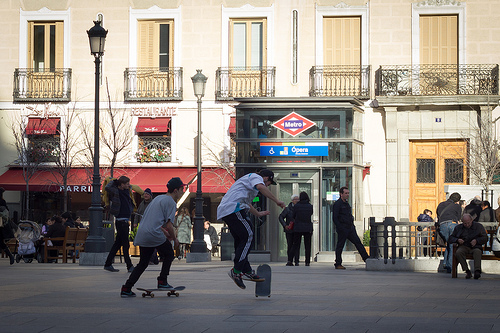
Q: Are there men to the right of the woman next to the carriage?
A: Yes, there is a man to the right of the woman.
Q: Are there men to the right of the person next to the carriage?
A: Yes, there is a man to the right of the woman.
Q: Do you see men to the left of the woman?
A: No, the man is to the right of the woman.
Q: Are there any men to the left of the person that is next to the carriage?
A: No, the man is to the right of the woman.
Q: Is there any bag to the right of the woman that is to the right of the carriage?
A: No, there is a man to the right of the woman.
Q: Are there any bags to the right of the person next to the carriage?
A: No, there is a man to the right of the woman.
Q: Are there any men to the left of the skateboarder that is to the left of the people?
A: Yes, there is a man to the left of the skateboarder.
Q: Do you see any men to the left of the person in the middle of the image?
A: Yes, there is a man to the left of the skateboarder.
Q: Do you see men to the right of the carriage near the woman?
A: Yes, there is a man to the right of the carriage.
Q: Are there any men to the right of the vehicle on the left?
A: Yes, there is a man to the right of the carriage.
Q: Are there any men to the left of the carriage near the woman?
A: No, the man is to the right of the carriage.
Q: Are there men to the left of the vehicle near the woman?
A: No, the man is to the right of the carriage.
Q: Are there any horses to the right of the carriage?
A: No, there is a man to the right of the carriage.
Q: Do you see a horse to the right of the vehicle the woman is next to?
A: No, there is a man to the right of the carriage.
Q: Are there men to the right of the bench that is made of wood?
A: Yes, there is a man to the right of the bench.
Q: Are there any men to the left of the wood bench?
A: No, the man is to the right of the bench.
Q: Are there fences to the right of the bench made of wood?
A: No, there is a man to the right of the bench.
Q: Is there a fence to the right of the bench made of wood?
A: No, there is a man to the right of the bench.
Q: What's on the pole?
A: The street light is on the pole.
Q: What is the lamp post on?
A: The lamp post is on the pole.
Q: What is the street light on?
A: The lamp post is on the pole.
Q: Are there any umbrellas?
A: No, there are no umbrellas.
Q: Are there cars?
A: No, there are no cars.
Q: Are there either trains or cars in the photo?
A: No, there are no cars or trains.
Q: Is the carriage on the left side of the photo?
A: Yes, the carriage is on the left of the image.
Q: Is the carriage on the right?
A: No, the carriage is on the left of the image.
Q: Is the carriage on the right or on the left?
A: The carriage is on the left of the image.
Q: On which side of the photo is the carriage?
A: The carriage is on the left of the image.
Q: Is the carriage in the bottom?
A: Yes, the carriage is in the bottom of the image.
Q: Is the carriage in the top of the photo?
A: No, the carriage is in the bottom of the image.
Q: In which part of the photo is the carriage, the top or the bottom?
A: The carriage is in the bottom of the image.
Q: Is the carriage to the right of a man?
A: No, the carriage is to the left of a man.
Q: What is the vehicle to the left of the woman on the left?
A: The vehicle is a carriage.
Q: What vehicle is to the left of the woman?
A: The vehicle is a carriage.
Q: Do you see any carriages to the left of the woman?
A: Yes, there is a carriage to the left of the woman.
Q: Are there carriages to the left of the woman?
A: Yes, there is a carriage to the left of the woman.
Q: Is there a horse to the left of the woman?
A: No, there is a carriage to the left of the woman.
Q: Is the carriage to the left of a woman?
A: Yes, the carriage is to the left of a woman.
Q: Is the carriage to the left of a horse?
A: No, the carriage is to the left of a woman.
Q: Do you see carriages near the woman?
A: Yes, there is a carriage near the woman.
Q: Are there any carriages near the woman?
A: Yes, there is a carriage near the woman.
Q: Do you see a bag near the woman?
A: No, there is a carriage near the woman.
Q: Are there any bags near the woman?
A: No, there is a carriage near the woman.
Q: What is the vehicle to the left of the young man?
A: The vehicle is a carriage.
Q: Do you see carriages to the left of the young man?
A: Yes, there is a carriage to the left of the man.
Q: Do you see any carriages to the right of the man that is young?
A: No, the carriage is to the left of the man.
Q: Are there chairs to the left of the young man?
A: No, there is a carriage to the left of the man.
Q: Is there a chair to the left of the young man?
A: No, there is a carriage to the left of the man.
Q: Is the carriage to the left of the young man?
A: Yes, the carriage is to the left of the man.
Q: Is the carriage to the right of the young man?
A: No, the carriage is to the left of the man.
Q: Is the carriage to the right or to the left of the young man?
A: The carriage is to the left of the man.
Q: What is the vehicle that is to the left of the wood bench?
A: The vehicle is a carriage.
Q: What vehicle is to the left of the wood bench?
A: The vehicle is a carriage.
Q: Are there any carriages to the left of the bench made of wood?
A: Yes, there is a carriage to the left of the bench.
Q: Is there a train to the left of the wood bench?
A: No, there is a carriage to the left of the bench.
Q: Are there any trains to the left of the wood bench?
A: No, there is a carriage to the left of the bench.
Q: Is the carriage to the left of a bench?
A: Yes, the carriage is to the left of a bench.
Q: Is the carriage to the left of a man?
A: Yes, the carriage is to the left of a man.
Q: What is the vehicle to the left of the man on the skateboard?
A: The vehicle is a carriage.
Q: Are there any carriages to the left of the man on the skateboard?
A: Yes, there is a carriage to the left of the man.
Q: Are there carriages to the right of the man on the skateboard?
A: No, the carriage is to the left of the man.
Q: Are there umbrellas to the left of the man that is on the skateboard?
A: No, there is a carriage to the left of the man.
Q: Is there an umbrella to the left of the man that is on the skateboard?
A: No, there is a carriage to the left of the man.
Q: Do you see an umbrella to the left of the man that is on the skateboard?
A: No, there is a carriage to the left of the man.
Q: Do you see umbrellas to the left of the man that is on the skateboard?
A: No, there is a carriage to the left of the man.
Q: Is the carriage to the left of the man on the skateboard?
A: Yes, the carriage is to the left of the man.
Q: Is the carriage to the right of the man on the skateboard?
A: No, the carriage is to the left of the man.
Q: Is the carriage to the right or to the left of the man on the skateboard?
A: The carriage is to the left of the man.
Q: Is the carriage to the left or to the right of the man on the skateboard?
A: The carriage is to the left of the man.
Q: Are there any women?
A: Yes, there is a woman.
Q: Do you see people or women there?
A: Yes, there is a woman.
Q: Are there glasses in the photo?
A: No, there are no glasses.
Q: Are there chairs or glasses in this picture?
A: No, there are no glasses or chairs.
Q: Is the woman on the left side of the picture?
A: Yes, the woman is on the left of the image.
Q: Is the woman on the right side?
A: No, the woman is on the left of the image.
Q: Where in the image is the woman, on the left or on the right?
A: The woman is on the left of the image.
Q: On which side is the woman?
A: The woman is on the left of the image.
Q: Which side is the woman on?
A: The woman is on the left of the image.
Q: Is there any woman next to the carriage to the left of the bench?
A: Yes, there is a woman next to the carriage.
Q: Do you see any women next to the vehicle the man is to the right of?
A: Yes, there is a woman next to the carriage.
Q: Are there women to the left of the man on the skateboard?
A: Yes, there is a woman to the left of the man.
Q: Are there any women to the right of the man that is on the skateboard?
A: No, the woman is to the left of the man.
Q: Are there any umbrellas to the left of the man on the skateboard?
A: No, there is a woman to the left of the man.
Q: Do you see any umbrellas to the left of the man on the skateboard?
A: No, there is a woman to the left of the man.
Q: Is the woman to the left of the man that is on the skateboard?
A: Yes, the woman is to the left of the man.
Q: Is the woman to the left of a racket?
A: No, the woman is to the left of the man.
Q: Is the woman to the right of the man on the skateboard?
A: No, the woman is to the left of the man.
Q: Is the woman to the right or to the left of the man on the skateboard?
A: The woman is to the left of the man.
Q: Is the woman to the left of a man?
A: Yes, the woman is to the left of a man.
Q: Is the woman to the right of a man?
A: No, the woman is to the left of a man.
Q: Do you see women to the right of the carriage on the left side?
A: Yes, there is a woman to the right of the carriage.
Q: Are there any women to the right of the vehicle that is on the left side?
A: Yes, there is a woman to the right of the carriage.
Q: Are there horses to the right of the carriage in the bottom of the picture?
A: No, there is a woman to the right of the carriage.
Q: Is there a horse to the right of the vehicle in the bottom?
A: No, there is a woman to the right of the carriage.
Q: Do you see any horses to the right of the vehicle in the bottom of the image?
A: No, there is a woman to the right of the carriage.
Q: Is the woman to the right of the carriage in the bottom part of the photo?
A: Yes, the woman is to the right of the carriage.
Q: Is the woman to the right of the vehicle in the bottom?
A: Yes, the woman is to the right of the carriage.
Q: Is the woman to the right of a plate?
A: No, the woman is to the right of the carriage.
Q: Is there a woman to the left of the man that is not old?
A: Yes, there is a woman to the left of the man.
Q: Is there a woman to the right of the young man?
A: No, the woman is to the left of the man.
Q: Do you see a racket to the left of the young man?
A: No, there is a woman to the left of the man.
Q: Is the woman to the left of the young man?
A: Yes, the woman is to the left of the man.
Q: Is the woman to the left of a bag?
A: No, the woman is to the left of the man.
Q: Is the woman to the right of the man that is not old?
A: No, the woman is to the left of the man.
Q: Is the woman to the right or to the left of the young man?
A: The woman is to the left of the man.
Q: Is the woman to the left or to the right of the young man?
A: The woman is to the left of the man.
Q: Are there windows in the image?
A: Yes, there is a window.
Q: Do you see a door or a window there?
A: Yes, there is a window.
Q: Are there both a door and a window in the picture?
A: Yes, there are both a window and a door.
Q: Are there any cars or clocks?
A: No, there are no cars or clocks.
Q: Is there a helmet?
A: No, there are no helmets.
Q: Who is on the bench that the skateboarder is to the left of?
A: The man is on the bench.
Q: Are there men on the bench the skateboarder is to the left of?
A: Yes, there is a man on the bench.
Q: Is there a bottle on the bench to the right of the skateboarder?
A: No, there is a man on the bench.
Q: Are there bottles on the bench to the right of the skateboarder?
A: No, there is a man on the bench.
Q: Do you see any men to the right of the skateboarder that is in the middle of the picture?
A: Yes, there is a man to the right of the skateboarder.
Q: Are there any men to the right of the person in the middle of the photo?
A: Yes, there is a man to the right of the skateboarder.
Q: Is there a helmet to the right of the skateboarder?
A: No, there is a man to the right of the skateboarder.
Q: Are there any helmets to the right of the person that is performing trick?
A: No, there is a man to the right of the skateboarder.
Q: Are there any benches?
A: Yes, there is a bench.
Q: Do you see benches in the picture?
A: Yes, there is a bench.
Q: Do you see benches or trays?
A: Yes, there is a bench.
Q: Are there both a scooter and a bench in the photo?
A: No, there is a bench but no scooters.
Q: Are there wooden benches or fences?
A: Yes, there is a wood bench.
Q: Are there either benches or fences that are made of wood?
A: Yes, the bench is made of wood.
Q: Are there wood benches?
A: Yes, there is a bench that is made of wood.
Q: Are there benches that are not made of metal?
A: Yes, there is a bench that is made of wood.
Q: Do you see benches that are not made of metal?
A: Yes, there is a bench that is made of wood.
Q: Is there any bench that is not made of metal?
A: Yes, there is a bench that is made of wood.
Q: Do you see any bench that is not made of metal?
A: Yes, there is a bench that is made of wood.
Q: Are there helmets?
A: No, there are no helmets.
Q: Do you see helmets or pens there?
A: No, there are no helmets or pens.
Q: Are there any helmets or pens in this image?
A: No, there are no helmets or pens.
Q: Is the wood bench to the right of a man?
A: No, the bench is to the left of a man.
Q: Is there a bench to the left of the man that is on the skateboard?
A: Yes, there is a bench to the left of the man.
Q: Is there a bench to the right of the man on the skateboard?
A: No, the bench is to the left of the man.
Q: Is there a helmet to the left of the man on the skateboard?
A: No, there is a bench to the left of the man.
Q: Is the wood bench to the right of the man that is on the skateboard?
A: No, the bench is to the left of the man.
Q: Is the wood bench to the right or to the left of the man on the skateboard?
A: The bench is to the left of the man.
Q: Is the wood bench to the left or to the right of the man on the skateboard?
A: The bench is to the left of the man.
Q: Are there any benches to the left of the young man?
A: Yes, there is a bench to the left of the man.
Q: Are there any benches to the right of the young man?
A: No, the bench is to the left of the man.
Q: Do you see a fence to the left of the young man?
A: No, there is a bench to the left of the man.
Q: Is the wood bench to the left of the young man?
A: Yes, the bench is to the left of the man.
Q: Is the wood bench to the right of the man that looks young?
A: No, the bench is to the left of the man.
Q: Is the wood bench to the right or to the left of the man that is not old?
A: The bench is to the left of the man.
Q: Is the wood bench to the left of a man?
A: Yes, the bench is to the left of a man.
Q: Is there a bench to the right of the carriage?
A: Yes, there is a bench to the right of the carriage.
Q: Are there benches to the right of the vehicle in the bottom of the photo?
A: Yes, there is a bench to the right of the carriage.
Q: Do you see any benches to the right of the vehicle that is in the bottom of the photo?
A: Yes, there is a bench to the right of the carriage.